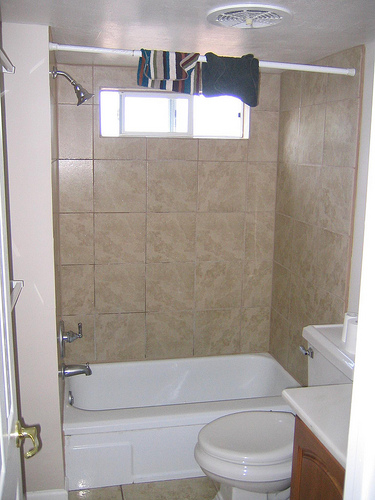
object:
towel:
[200, 51, 262, 109]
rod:
[50, 42, 355, 81]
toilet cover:
[198, 409, 297, 465]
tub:
[66, 355, 297, 413]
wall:
[56, 65, 282, 367]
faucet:
[62, 362, 94, 380]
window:
[121, 87, 194, 140]